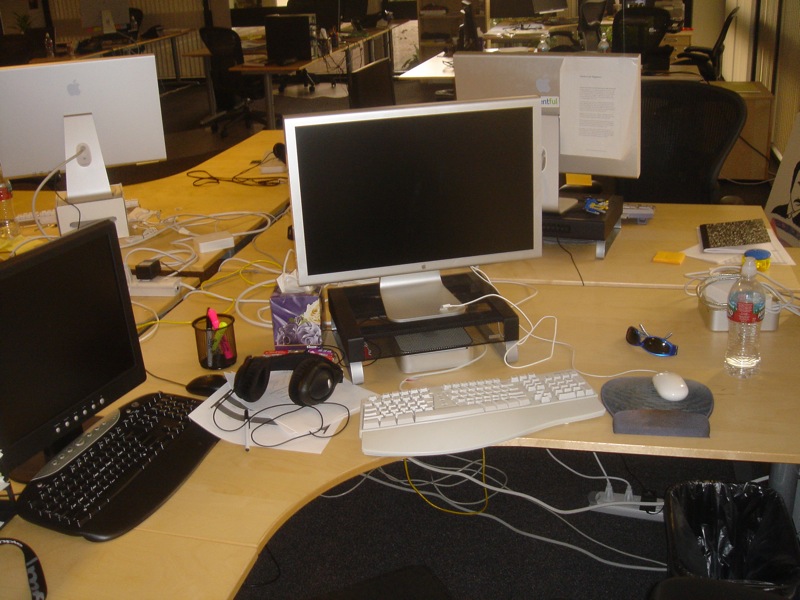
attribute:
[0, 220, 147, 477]
monitor — black, of computer desktop, black screened, largest, front visible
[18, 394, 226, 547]
keyboard — black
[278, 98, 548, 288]
monitor — silver, of desktop computer, black, white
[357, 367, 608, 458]
keyboard — white, ergonomic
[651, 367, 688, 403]
mouse — white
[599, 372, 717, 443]
pad — gray, grey, worn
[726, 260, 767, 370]
bottle — clear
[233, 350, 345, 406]
headphones — black, sony, noise cancelling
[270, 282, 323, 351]
kleenex box — purple, black, yellow, white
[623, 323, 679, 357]
sunglasses — blue, black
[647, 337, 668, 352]
lenses — black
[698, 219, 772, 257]
notebook — black, white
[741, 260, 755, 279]
lid — white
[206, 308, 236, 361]
highlighter — pink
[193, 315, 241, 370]
cup — small, black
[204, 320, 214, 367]
highlighter — white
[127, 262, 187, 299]
surge protector — white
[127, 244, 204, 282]
cords — white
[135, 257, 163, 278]
cord — black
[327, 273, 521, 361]
stand — black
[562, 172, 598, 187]
post-it — yellow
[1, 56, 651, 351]
desktop computers — apple